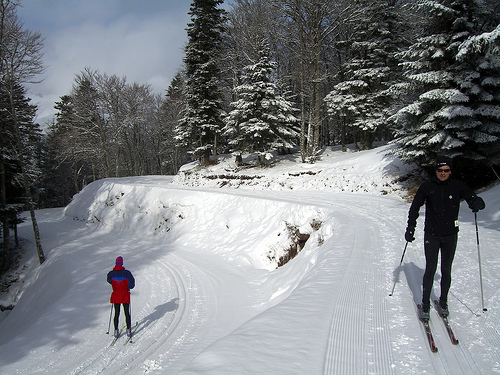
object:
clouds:
[2, 0, 239, 136]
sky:
[2, 1, 331, 136]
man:
[405, 155, 486, 322]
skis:
[416, 300, 459, 353]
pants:
[422, 231, 458, 304]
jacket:
[406, 175, 478, 236]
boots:
[419, 301, 449, 322]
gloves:
[405, 197, 485, 242]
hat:
[434, 155, 453, 172]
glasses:
[436, 169, 450, 173]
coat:
[107, 264, 135, 304]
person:
[107, 256, 135, 338]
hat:
[115, 256, 123, 265]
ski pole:
[471, 195, 488, 312]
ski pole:
[388, 231, 413, 297]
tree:
[221, 32, 303, 168]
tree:
[374, 0, 500, 176]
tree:
[321, 0, 414, 150]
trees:
[0, 72, 55, 266]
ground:
[2, 137, 498, 373]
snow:
[1, 138, 500, 375]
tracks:
[40, 195, 496, 373]